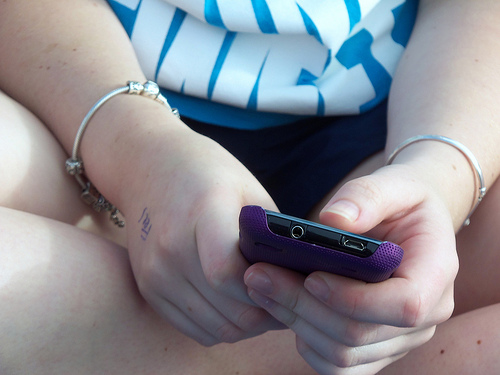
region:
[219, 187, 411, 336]
a phone with a cover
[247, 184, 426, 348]
a phone with a purple cover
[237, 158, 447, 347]
a cell phone with a cover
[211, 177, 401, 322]
a cell phone with purple cover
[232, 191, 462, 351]
cover on a phone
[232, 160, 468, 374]
purple cover on cell phone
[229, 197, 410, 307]
purple cover on cell phone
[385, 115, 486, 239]
metal bracelet on wrist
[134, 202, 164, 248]
tattoo on back of hand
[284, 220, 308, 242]
ear phone jack on cell phone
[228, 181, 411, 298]
black and silver cell phone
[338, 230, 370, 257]
power input on cell phone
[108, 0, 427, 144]
blue and white shirt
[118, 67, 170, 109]
charms on metal bracelet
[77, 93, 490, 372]
two hands holding cell phone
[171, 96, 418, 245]
pair of blue shorts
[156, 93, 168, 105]
silver bead on bracelet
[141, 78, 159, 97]
silver bead on bracelet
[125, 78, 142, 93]
silver bead on bracelet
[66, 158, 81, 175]
silver bead on bracelet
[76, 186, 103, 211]
silver bead on bracelet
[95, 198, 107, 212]
silver bead on bracelet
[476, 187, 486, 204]
silver bead on bracelet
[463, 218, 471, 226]
silver bead on bracelet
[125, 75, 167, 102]
silver beads on bracelet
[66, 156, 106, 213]
silver beads on bracelet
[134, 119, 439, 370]
Female hands hold cell phone.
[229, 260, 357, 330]
Fingernails neatly trimmed and clean.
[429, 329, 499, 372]
Two freckles left leg.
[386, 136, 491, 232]
Thin silver bracelet left wrist.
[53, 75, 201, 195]
Silver beaded bracelet right wrist.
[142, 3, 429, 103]
Blue and white t-shirt.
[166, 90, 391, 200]
Dark blue summer shorts.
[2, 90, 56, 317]
Sunlight shines folded right leg.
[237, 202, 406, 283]
Cell phone in purple case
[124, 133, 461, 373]
Person's hands holding a cell phone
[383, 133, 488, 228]
Silver bracelet on person's arm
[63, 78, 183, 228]
Silver bracelet with sliding beads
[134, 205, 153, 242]
Small tattoo or ink drawing on back of person's hand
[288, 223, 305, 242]
Headphone or microphone port of cell phone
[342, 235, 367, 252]
Mini-USB port in top of cell phone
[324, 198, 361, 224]
Short, clean thumbnail on left hand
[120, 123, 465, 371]
A cell phone in two hands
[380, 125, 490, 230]
A bracelet around a wrist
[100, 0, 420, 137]
White writing on a blue shirt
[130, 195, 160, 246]
A tattoo on a hand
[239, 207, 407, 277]
A black cellphone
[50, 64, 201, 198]
The left bracelet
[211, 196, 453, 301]
Black cellphone in purple case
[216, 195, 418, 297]
Cellphone in purple case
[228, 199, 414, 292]
Black phone in purple case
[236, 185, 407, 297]
Phone in purple case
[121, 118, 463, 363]
Phone in woman's hands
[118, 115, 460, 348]
Cellphone in woman's hands